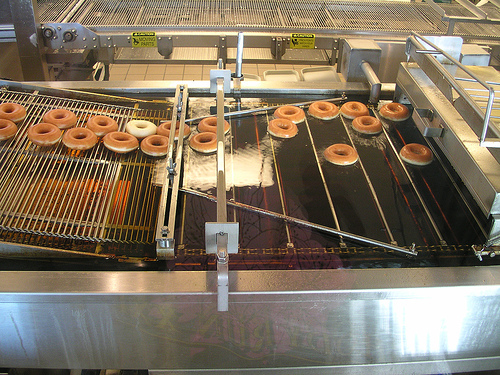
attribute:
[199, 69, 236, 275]
rod — metal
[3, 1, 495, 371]
facility — donut-making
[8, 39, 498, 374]
machinery — donut-making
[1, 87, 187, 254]
conveyor belt — steel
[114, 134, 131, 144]
center — white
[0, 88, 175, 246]
conveyor belt — hot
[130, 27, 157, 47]
warning sign — yellow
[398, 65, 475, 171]
machinery — metal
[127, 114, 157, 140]
donut — uncooked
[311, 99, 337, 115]
top — brown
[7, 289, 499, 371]
surface — metal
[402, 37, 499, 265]
mechanism — metal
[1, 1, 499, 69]
portion — unused